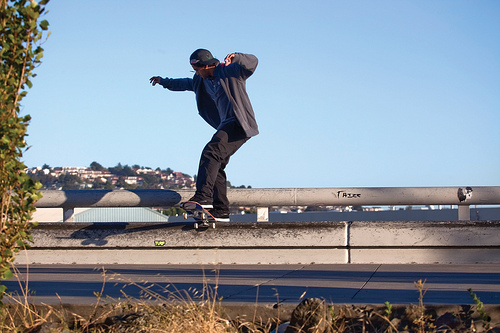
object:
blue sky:
[0, 0, 499, 189]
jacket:
[159, 52, 259, 137]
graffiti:
[338, 191, 361, 199]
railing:
[0, 186, 500, 207]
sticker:
[154, 240, 166, 246]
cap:
[189, 49, 219, 66]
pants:
[193, 120, 251, 217]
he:
[149, 49, 260, 222]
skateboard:
[182, 201, 217, 228]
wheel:
[183, 213, 188, 219]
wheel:
[194, 223, 198, 228]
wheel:
[201, 213, 205, 220]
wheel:
[212, 223, 215, 229]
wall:
[11, 221, 500, 265]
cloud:
[22, 0, 500, 151]